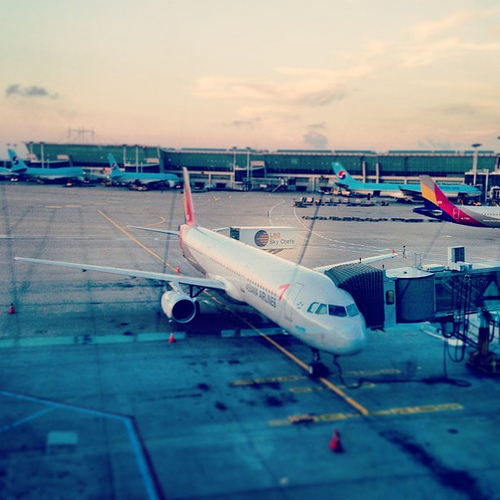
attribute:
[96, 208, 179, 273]
line — yellow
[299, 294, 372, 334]
cock pit — large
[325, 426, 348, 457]
cone — orange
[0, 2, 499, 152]
sky — pink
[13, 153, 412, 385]
airplane — white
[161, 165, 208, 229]
tail — red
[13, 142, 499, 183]
building — terminal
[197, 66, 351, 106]
clouds — white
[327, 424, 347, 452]
caution cone — orange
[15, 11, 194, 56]
sky — colorful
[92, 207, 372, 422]
line — yellow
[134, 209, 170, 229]
line — yellow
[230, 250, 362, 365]
commercial plane — large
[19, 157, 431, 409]
jet — white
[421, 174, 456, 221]
tail fin — blue, yellow, red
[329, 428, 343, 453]
cone — orange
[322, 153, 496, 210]
jet — large, blue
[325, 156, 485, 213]
airplane — blue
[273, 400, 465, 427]
line — yellow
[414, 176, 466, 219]
tail fin — colorful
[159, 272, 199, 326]
engine — large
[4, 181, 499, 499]
surface — gray, concrete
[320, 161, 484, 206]
plane — blue